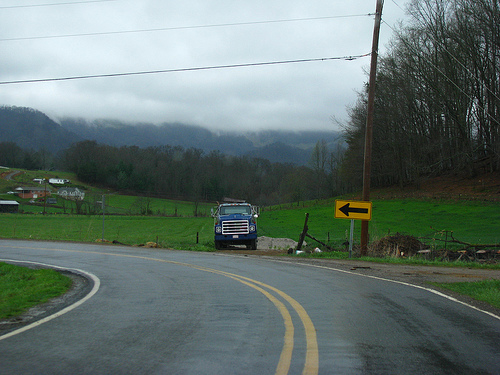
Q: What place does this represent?
A: It represents the road.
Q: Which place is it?
A: It is a road.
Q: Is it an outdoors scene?
A: Yes, it is outdoors.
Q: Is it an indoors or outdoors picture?
A: It is outdoors.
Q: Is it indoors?
A: No, it is outdoors.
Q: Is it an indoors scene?
A: No, it is outdoors.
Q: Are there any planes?
A: No, there are no planes.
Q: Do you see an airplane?
A: No, there are no airplanes.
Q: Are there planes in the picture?
A: No, there are no planes.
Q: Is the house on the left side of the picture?
A: Yes, the house is on the left of the image.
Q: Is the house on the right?
A: No, the house is on the left of the image.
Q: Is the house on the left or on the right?
A: The house is on the left of the image.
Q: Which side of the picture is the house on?
A: The house is on the left of the image.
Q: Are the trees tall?
A: Yes, the trees are tall.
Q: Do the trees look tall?
A: Yes, the trees are tall.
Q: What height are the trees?
A: The trees are tall.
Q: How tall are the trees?
A: The trees are tall.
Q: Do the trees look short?
A: No, the trees are tall.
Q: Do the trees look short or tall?
A: The trees are tall.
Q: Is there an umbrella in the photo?
A: No, there are no umbrellas.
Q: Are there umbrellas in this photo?
A: No, there are no umbrellas.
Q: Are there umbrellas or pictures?
A: No, there are no umbrellas or pictures.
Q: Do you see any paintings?
A: No, there are no paintings.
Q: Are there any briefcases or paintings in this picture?
A: No, there are no paintings or briefcases.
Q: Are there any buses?
A: No, there are no buses.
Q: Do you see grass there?
A: Yes, there is grass.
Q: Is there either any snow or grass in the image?
A: Yes, there is grass.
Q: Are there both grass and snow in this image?
A: No, there is grass but no snow.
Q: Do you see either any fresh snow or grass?
A: Yes, there is fresh grass.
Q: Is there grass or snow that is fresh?
A: Yes, the grass is fresh.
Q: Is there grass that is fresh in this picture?
A: Yes, there is fresh grass.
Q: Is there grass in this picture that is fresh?
A: Yes, there is grass that is fresh.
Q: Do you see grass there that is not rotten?
A: Yes, there is fresh grass.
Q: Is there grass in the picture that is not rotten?
A: Yes, there is fresh grass.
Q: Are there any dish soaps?
A: No, there are no dish soaps.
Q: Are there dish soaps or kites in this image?
A: No, there are no dish soaps or kites.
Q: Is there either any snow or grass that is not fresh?
A: No, there is grass but it is fresh.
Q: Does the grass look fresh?
A: Yes, the grass is fresh.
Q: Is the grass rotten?
A: No, the grass is fresh.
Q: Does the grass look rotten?
A: No, the grass is fresh.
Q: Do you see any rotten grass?
A: No, there is grass but it is fresh.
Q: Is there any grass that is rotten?
A: No, there is grass but it is fresh.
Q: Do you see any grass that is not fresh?
A: No, there is grass but it is fresh.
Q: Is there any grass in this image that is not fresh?
A: No, there is grass but it is fresh.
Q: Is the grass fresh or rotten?
A: The grass is fresh.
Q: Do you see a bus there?
A: No, there are no buses.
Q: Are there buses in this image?
A: No, there are no buses.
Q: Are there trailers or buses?
A: No, there are no buses or trailers.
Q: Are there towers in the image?
A: No, there are no towers.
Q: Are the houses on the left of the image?
A: Yes, the houses are on the left of the image.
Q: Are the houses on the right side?
A: No, the houses are on the left of the image.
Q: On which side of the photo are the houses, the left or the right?
A: The houses are on the left of the image.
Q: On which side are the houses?
A: The houses are on the left of the image.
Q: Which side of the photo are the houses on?
A: The houses are on the left of the image.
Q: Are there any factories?
A: No, there are no factories.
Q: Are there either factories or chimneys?
A: No, there are no factories or chimneys.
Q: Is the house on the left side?
A: Yes, the house is on the left of the image.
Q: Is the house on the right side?
A: No, the house is on the left of the image.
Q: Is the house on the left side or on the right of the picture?
A: The house is on the left of the image.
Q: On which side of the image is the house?
A: The house is on the left of the image.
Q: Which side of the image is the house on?
A: The house is on the left of the image.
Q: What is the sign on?
A: The sign is on the pole.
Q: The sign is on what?
A: The sign is on the pole.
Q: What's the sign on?
A: The sign is on the pole.